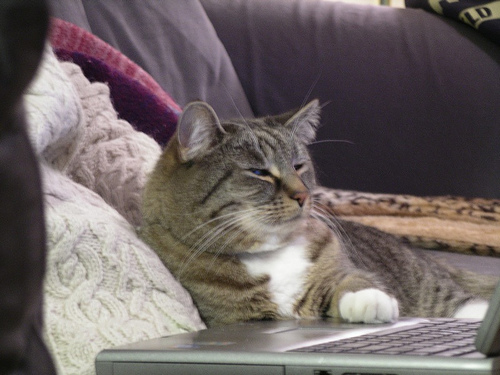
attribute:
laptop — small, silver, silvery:
[86, 294, 498, 375]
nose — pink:
[287, 186, 312, 210]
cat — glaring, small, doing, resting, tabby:
[137, 90, 495, 322]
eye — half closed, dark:
[247, 167, 271, 179]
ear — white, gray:
[173, 96, 229, 166]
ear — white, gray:
[273, 96, 325, 152]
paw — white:
[338, 286, 409, 327]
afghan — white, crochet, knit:
[15, 36, 185, 375]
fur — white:
[239, 233, 314, 319]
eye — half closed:
[290, 160, 309, 174]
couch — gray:
[49, 3, 499, 323]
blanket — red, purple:
[48, 16, 182, 145]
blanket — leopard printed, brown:
[308, 185, 499, 256]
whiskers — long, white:
[175, 203, 278, 276]